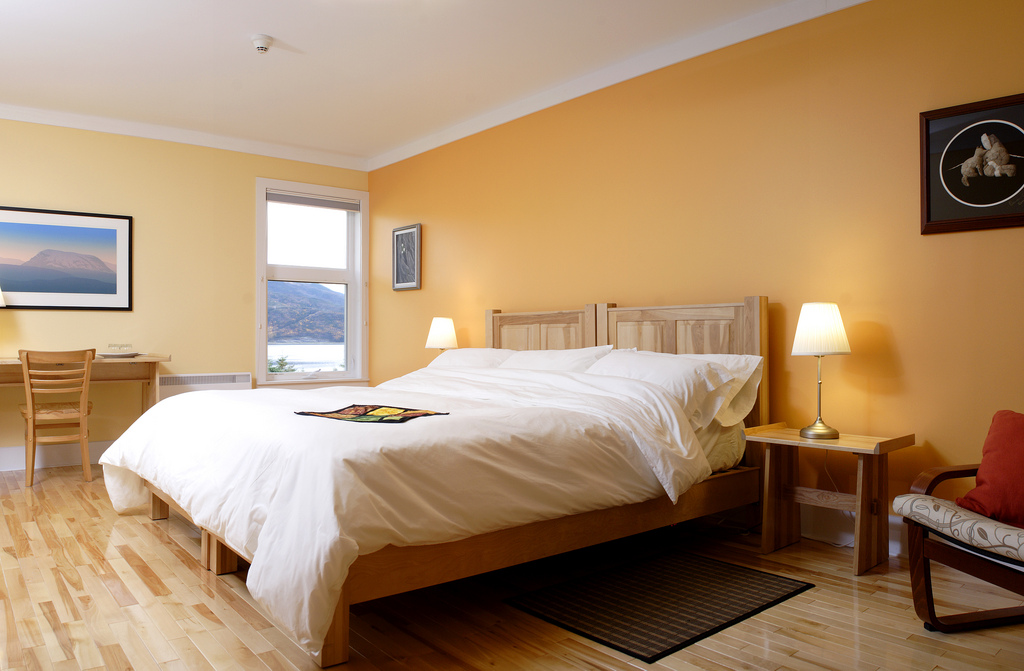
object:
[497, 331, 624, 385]
pillow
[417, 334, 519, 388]
pillow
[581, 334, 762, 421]
pillow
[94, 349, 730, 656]
blanket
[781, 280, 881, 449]
lamp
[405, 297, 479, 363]
lamp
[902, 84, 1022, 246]
picture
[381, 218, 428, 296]
picture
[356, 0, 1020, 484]
wall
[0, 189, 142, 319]
picture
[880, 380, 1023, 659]
chair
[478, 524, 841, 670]
rug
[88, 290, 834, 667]
bed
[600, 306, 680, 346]
panel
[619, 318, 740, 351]
panel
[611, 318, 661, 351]
panel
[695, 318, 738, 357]
panel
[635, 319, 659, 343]
panel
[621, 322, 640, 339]
panel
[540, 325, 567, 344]
panel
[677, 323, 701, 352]
panel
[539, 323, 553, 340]
panel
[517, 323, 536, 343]
panel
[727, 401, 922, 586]
stand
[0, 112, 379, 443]
wall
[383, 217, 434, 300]
picture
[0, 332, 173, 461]
desk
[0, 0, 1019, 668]
room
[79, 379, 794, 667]
frame